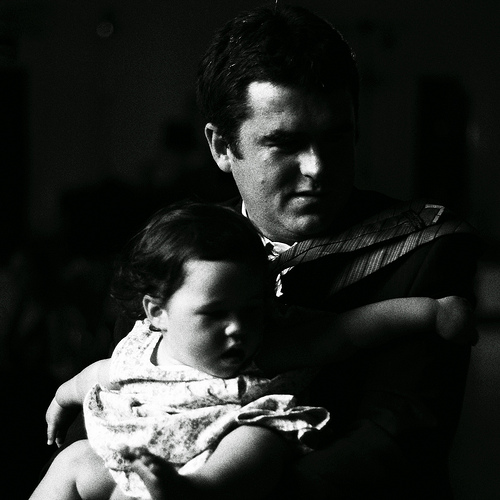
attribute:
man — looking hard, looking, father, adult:
[108, 1, 481, 499]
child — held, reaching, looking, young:
[24, 198, 484, 499]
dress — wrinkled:
[82, 317, 333, 496]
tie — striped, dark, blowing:
[270, 199, 478, 311]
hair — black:
[197, 3, 363, 163]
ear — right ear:
[202, 119, 236, 174]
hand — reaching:
[435, 296, 482, 351]